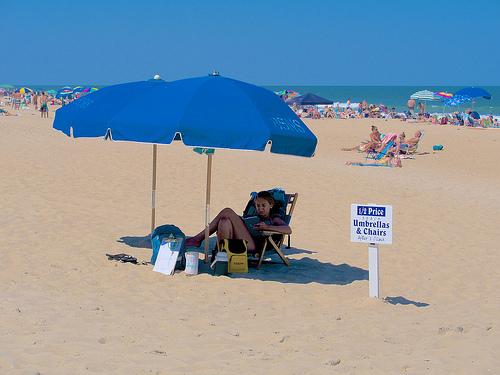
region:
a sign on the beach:
[331, 180, 429, 324]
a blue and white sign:
[316, 170, 430, 304]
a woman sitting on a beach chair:
[191, 169, 381, 304]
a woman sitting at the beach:
[138, 142, 373, 324]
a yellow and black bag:
[202, 222, 282, 307]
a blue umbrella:
[57, 49, 393, 238]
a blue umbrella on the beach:
[38, 27, 405, 361]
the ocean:
[226, 60, 498, 132]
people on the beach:
[308, 82, 486, 205]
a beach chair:
[230, 182, 297, 297]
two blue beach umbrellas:
[47, 56, 318, 166]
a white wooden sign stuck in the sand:
[330, 195, 410, 305]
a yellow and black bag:
[220, 240, 256, 270]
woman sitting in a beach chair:
[170, 161, 311, 261]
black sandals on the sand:
[100, 245, 135, 270]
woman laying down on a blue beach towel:
[342, 148, 427, 173]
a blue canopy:
[287, 90, 333, 106]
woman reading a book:
[223, 182, 293, 250]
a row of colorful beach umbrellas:
[15, 73, 100, 93]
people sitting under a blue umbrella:
[436, 82, 498, 131]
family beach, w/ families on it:
[1, 68, 498, 328]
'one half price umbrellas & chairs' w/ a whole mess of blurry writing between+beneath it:
[345, 195, 400, 301]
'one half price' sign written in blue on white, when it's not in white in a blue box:
[341, 200, 396, 302]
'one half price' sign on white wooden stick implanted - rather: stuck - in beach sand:
[340, 195, 400, 306]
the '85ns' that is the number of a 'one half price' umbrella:
[259, 106, 309, 136]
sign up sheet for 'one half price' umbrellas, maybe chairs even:
[145, 226, 186, 281]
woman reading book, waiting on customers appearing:
[178, 186, 293, 267]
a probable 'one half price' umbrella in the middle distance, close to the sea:
[445, 79, 495, 126]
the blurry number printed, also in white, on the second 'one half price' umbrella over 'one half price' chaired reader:
[67, 92, 97, 114]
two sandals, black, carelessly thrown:
[100, 246, 141, 271]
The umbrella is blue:
[81, 75, 311, 173]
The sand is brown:
[94, 279, 262, 357]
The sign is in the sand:
[324, 182, 401, 311]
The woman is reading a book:
[180, 185, 326, 262]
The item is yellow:
[215, 225, 258, 295]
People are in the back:
[333, 116, 426, 176]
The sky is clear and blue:
[330, 21, 447, 89]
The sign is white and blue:
[343, 197, 417, 248]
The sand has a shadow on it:
[379, 281, 480, 355]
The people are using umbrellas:
[362, 49, 488, 127]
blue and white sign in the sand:
[348, 203, 396, 296]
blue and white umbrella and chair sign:
[350, 202, 395, 300]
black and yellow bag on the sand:
[216, 236, 252, 276]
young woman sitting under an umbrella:
[173, 186, 298, 271]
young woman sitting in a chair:
[180, 188, 300, 273]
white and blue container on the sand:
[181, 247, 199, 278]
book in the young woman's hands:
[237, 211, 264, 233]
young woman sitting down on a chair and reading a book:
[182, 186, 304, 273]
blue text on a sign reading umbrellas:
[351, 220, 390, 227]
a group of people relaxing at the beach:
[343, 118, 434, 173]